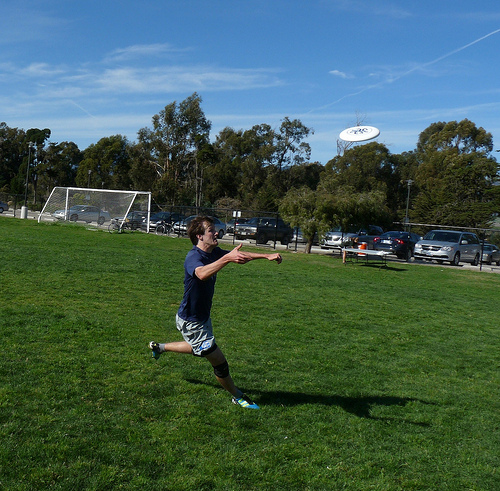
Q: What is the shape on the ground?
A: The shadow of the man.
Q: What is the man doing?
A: About to catch the frisbee.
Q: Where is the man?
A: On a grass field.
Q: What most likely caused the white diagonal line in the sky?
A: A plane.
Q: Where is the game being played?
A: Green field.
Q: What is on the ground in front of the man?
A: Shadow of the man.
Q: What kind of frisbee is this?
A: Round white frisbee.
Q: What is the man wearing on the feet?
A: Sneakers.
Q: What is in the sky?
A: Clouds.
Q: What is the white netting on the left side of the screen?
A: Soccer goal.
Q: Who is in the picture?
A: A man.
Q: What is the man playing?
A: Frisbee.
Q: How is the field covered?
A: With grass.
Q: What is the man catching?
A: A frisbee.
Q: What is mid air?
A: A frisbee.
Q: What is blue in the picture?
A: The sky.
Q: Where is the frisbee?
A: Mid air.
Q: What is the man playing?
A: Frisbee.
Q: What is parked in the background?
A: Cars.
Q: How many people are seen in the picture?
A: One.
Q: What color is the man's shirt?
A: Blue.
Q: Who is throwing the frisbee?
A: A man.